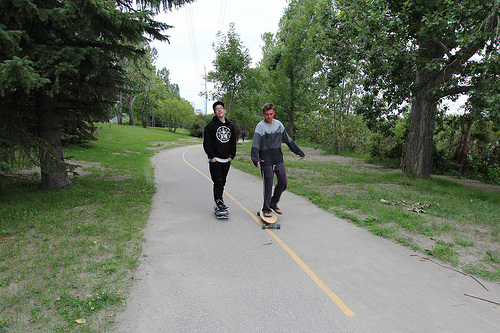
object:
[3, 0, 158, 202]
tree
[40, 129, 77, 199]
trunk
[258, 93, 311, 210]
boy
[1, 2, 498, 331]
park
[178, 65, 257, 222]
guy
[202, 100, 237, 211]
boy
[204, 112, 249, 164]
sweatshirt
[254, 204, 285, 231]
skateboard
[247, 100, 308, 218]
guy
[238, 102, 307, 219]
someone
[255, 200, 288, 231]
skateboard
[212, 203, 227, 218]
skateboard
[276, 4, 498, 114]
tall trees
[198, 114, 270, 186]
hoodie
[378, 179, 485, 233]
grass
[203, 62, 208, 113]
pole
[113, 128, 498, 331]
path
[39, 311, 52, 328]
dirt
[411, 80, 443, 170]
trunk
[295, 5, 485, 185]
tree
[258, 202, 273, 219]
feet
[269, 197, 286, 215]
feet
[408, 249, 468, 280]
limbs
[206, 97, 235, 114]
black cap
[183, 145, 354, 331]
line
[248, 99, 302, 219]
they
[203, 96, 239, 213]
they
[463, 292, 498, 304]
stick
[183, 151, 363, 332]
yellow line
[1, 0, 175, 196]
trees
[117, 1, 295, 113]
sky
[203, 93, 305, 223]
people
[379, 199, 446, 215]
wood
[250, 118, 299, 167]
sweater